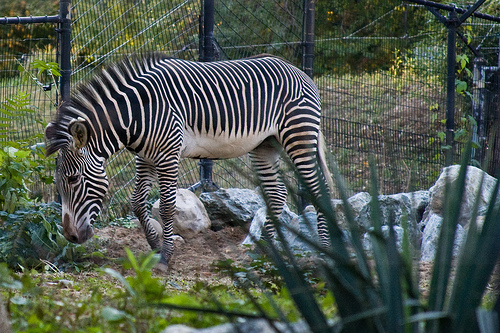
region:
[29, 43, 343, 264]
black and white zebra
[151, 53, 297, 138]
thin black and white stripes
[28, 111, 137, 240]
head bent down towards the ground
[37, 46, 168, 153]
hair along the neck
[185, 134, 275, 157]
underbelly is plain white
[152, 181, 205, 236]
boulder on the dirt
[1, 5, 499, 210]
chain link fence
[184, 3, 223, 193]
black post on the fence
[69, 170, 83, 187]
eye on the side of the face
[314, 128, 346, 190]
white hair on the tail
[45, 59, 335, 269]
A stripped zebra in the park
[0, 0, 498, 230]
An enclosed area in a zoo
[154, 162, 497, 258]
The gray rocks in the park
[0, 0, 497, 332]
An enclosed animal zoo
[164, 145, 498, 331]
Sisal like plant on the right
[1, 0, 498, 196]
The metallic fencing bars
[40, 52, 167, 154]
The zebra's stripped neck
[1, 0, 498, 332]
A bright day in the park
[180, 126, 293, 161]
The zebra's unmarked abdomen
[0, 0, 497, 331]
Green plants in a park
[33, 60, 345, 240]
the stripes are black and white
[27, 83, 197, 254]
the zebra is looking down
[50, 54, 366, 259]
A zebra in a zoo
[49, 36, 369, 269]
A zebra sniffing a plant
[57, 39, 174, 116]
The short mane of the zebra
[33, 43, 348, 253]
The zebra has stripes all over its body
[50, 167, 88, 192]
Open eyes on the zebra's face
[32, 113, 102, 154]
Two ears on the zebra's head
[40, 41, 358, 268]
The zebra is colored black and white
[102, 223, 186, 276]
Dirt beneath the hooves of the zebra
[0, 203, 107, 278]
A small, leafy green plant on the ground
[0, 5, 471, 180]
A thin black fence behind the zebra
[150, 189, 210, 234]
white irregular shaped rock behind zebra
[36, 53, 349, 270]
zebra standing in front of fence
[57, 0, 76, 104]
black metal fence post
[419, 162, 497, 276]
large gray rock to the right of zebra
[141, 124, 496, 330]
large green spiky plant in front of rock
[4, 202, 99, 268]
green plant behind zebra head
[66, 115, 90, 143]
ear on zebra head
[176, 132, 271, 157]
white belly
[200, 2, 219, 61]
fence post to the right of fence post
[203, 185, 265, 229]
rock next to rock